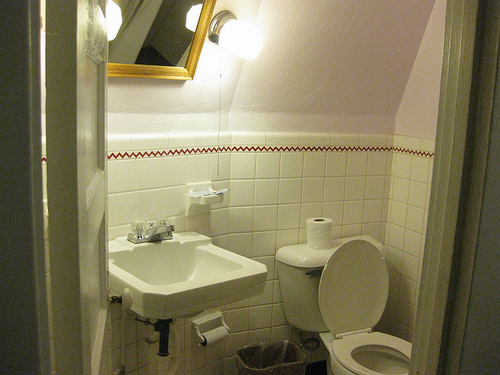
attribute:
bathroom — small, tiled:
[72, 126, 477, 371]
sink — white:
[117, 246, 271, 306]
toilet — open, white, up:
[323, 318, 428, 374]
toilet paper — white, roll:
[300, 214, 335, 244]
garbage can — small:
[233, 337, 315, 375]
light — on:
[213, 6, 292, 71]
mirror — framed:
[107, 9, 210, 84]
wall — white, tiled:
[125, 0, 432, 214]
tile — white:
[255, 156, 391, 233]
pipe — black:
[151, 327, 173, 362]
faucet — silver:
[126, 216, 183, 245]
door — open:
[59, 21, 123, 324]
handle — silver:
[303, 262, 323, 284]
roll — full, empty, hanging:
[204, 324, 233, 347]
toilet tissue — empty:
[303, 208, 348, 252]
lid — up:
[329, 263, 386, 325]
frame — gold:
[102, 62, 205, 83]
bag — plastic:
[263, 349, 301, 366]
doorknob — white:
[108, 282, 140, 314]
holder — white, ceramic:
[193, 310, 227, 327]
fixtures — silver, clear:
[128, 222, 169, 235]